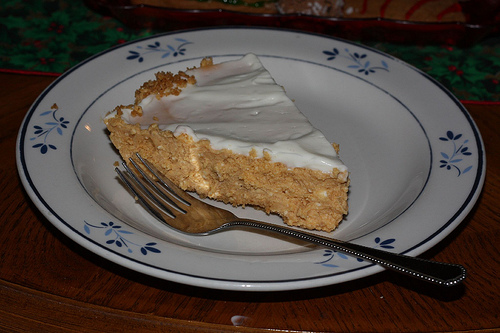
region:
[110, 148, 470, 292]
A fork sitting on a plate.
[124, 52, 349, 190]
a slice of pie with white frosting.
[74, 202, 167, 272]
flowers on a white plate.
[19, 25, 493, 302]
a white plate with pie.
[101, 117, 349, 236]
the side of a piece of pie.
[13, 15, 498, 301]
a plate of food on a table.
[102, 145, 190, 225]
prongs on a fork.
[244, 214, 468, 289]
A handle on a fork.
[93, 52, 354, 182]
icing on a cake.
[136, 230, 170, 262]
leaves on a plate.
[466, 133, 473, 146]
part of a plate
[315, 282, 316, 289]
edge of a plate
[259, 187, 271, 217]
piece of a cake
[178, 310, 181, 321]
edge of a table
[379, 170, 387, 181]
side of a plate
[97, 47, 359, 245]
slice of peanut butter pie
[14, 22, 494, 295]
shiny white plate with blue floral print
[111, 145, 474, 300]
shiny stainless steel fork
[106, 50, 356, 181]
layer of whipped cream on peanut butter pie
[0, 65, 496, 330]
deep wood grain table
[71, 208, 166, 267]
light and dark blue floral print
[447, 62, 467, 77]
two red holly berries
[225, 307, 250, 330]
white smudge on the table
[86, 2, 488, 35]
long transparent dish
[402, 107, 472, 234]
White plate with blue flowers.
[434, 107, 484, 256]
Dark blue rim on the plate.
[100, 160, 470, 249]
Silver fork on the plate.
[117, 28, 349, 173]
White topping on the pie.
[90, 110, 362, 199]
This looks like a chiffon pumpkin pie.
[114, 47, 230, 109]
The pie has a crumb shell.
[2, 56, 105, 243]
The plate is on a wooden table.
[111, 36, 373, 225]
This pie was made at home.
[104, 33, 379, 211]
The pie will make a great desert.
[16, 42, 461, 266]
piece of pie on saucer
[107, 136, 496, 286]
silver fork laying next to pie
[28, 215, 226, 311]
floral design on plate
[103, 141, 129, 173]
small crumb on plate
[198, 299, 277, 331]
smudge on table next to plate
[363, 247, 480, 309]
shadow of fork on table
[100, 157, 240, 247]
reflection of pie on fork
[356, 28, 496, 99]
place mat with leaves and holly design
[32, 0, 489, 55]
platter in center of table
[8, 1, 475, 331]
small saucer of pie sitting on dark wood table